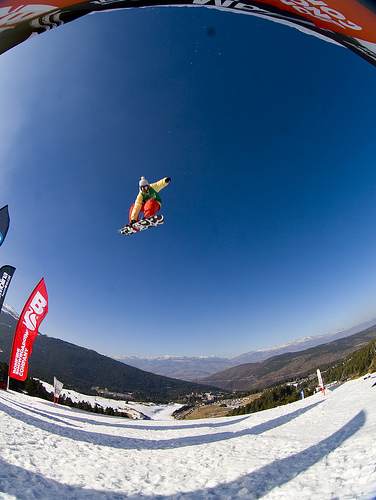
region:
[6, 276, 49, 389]
Red flag with white letters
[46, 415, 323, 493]
White show with shadows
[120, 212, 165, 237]
Black and white snowboard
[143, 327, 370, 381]
Mountain ranges in the distance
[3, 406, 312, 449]
Snow with shadows cast from event flags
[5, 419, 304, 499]
Several footprints in snow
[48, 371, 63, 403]
Flag barrier on a ski slope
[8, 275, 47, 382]
Red and white sponsership flag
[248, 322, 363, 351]
Snow-capped mountain range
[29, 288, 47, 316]
White "B" against red background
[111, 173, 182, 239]
a snowboarder flying through the air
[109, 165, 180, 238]
a snowboarder performing a trick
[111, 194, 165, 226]
snowboarder's orange pants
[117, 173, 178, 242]
snowboarder gripping their board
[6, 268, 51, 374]
A tall red banner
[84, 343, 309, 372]
mountains in the horizon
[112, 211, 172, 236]
black and white snowboard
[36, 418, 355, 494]
lots of white snow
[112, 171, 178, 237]
snowboarder several feet off the ground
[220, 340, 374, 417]
trees lining the snowboarding path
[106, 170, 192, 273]
snowboarder in the air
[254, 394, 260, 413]
evergreen tree along slope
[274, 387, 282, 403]
evergreen tree along slope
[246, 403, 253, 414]
evergreen tree along slope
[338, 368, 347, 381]
evergreen tree along slope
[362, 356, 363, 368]
evergreen tree along slope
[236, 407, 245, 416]
evergreen tree along slope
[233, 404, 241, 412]
evergreen tree along slope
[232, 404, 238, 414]
evergreen tree along slope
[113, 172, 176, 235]
snowboarder floating in the sky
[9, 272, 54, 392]
red banner with white letters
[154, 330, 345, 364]
snow covered mountain ranges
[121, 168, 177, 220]
snowboarder wearing goggles and snow outfit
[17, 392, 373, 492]
snow area for snowboarding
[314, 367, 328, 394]
standing white and red banner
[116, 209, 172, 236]
white and black snowboard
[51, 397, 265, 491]
snowy passage way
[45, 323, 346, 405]
various mountain ranges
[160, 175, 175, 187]
snowboarders black gloved hand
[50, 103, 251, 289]
guy in the air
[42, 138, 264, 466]
guy on a snowboard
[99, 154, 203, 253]
guy wearing a beanie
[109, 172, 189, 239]
guy wearing a puffer jacket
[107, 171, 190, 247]
guy wearing orange pants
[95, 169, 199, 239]
guy right hand on the snowboard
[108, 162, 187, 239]
guy wearing a mask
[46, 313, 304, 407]
brown mountains with snow on top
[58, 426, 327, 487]
white snow